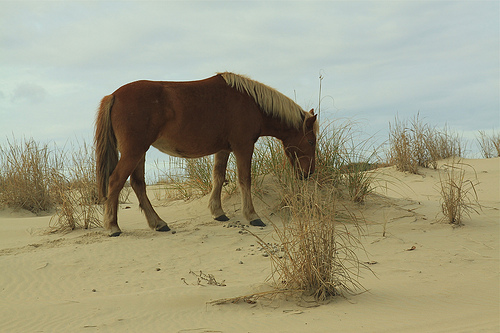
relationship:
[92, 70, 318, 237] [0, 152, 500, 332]
horse in sand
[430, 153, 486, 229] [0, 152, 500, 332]
bush growing from sand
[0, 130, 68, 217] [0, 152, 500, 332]
grass growing from sand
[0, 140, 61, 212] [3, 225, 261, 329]
grass growing from sand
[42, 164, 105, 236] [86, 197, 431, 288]
bush growing from sand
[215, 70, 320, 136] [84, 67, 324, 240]
mane on horse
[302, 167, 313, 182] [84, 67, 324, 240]
nose on horse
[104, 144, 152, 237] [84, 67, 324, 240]
leg are on horse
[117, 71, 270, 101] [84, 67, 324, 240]
back on horse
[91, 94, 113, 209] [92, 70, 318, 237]
tail on horse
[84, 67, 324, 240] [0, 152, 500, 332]
horse standing on sand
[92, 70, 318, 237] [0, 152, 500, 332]
horse standing on sand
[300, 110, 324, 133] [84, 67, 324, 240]
ear on horse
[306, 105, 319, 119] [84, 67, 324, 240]
ear on horse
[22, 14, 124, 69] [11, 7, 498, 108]
clouds are in sky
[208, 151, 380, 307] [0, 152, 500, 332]
bunch growing from sand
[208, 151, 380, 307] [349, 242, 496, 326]
bunch growing from sand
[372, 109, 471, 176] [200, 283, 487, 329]
bush growing from sand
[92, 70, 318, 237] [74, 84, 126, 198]
horse has tail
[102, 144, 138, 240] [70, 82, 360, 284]
leg of horse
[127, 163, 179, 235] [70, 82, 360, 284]
leg of horse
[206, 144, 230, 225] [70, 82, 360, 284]
leg of horse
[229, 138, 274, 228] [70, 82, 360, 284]
leg of horse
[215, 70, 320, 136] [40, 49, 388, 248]
mane of horse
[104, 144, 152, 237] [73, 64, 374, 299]
leg of horse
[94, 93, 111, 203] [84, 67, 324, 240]
tail of horse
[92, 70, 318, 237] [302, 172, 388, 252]
horse eating grass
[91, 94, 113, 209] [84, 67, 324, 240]
tail of horse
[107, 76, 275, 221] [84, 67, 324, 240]
body of horse